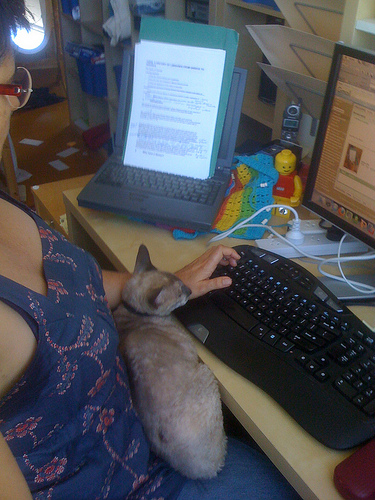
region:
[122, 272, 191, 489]
Cat in front of a computer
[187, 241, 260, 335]
Woman typing on a keyboard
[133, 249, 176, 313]
cat looking at a computer screen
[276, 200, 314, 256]
Power cord plugged in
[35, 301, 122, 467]
woman wearing a floral shirt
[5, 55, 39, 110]
Woman wearing glasses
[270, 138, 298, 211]
Yellow toy on a desk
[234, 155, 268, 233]
Crochet cloth on a desk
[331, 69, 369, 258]
Woman looking at a computer screen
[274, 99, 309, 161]
cordless phone on a desk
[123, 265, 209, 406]
a cat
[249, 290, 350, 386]
a black keyboard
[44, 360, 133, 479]
the women is wearing a blue and red tank top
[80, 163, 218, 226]
keyboard on the laptop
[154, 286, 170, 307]
the cats ear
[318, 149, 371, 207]
a computer screen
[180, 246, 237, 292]
the womens hand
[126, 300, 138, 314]
the cats collar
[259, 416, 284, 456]
a wooden desk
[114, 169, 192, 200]
a keyboard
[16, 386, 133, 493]
Blue shirt with red flower design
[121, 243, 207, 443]
Cat laying on woman's lap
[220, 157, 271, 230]
Crocheted blanket in primary colors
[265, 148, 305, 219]
Large size lego man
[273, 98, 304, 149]
Black and gray telephone on desk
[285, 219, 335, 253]
Two white power strips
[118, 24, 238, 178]
Papers leaning on an open laptop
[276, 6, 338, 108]
Files on wall behind desk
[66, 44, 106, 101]
Blue tote in cubicle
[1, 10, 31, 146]
Woman wearing glasses with red fram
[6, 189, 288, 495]
Woman sitting at desk in front of computer.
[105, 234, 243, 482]
Cat sitting on woman's lap.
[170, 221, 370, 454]
Computer keyboard sitting on desk.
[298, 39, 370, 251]
Computer monitor sitting on desk.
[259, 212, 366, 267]
Electrical outlet strip sitting on desk.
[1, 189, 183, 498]
Woman dressed in blue tank top with pink flower design.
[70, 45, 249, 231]
Laptop computer sitting on desk.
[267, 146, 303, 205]
Yellow and red plastic toy sitting on desk.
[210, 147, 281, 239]
Portion of a blue, yellow, red and green knit blanket lying on desk.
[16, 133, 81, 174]
Envelopes spread out over floor.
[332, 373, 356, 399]
Black and white key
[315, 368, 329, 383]
Black and white key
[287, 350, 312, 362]
Black and white key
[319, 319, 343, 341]
Black and white key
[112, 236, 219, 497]
Cat sitting on lap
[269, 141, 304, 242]
Small yellow and red lego man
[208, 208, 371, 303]
Cord to a surge protector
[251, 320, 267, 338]
Black and white key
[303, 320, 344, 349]
Black and white key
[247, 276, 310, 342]
Black and white key